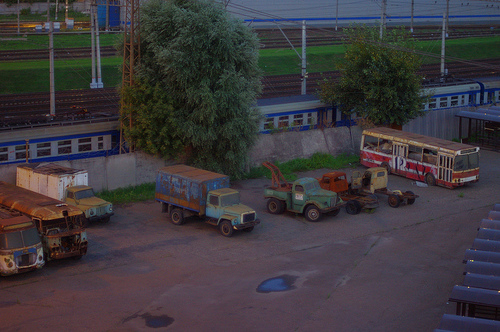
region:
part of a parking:
[428, 234, 443, 246]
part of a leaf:
[236, 134, 256, 154]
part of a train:
[298, 115, 300, 119]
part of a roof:
[464, 260, 474, 288]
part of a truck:
[219, 201, 226, 216]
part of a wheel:
[300, 212, 311, 222]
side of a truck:
[184, 186, 196, 196]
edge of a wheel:
[218, 218, 223, 229]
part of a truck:
[406, 153, 411, 163]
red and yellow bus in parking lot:
[348, 119, 484, 194]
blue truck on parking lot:
[142, 157, 262, 238]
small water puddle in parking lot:
[244, 261, 306, 299]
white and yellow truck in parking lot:
[8, 157, 123, 227]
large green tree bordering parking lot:
[123, 0, 260, 174]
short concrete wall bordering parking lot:
[1, 93, 497, 210]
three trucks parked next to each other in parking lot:
[255, 155, 425, 224]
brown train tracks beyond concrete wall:
[2, 16, 498, 63]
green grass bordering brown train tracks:
[1, 25, 496, 69]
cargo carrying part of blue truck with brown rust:
[152, 155, 231, 236]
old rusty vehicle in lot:
[362, 103, 462, 195]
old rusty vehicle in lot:
[4, 213, 48, 270]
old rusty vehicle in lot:
[39, 192, 96, 272]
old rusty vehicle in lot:
[72, 152, 148, 252]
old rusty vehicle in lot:
[166, 156, 248, 233]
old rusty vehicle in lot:
[257, 181, 340, 226]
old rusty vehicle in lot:
[332, 170, 362, 212]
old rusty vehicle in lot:
[372, 163, 431, 213]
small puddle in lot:
[224, 264, 321, 310]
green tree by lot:
[136, 26, 250, 154]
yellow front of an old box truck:
[61, 179, 111, 224]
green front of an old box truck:
[207, 178, 258, 235]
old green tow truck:
[260, 161, 340, 231]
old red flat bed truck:
[317, 165, 379, 213]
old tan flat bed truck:
[361, 161, 413, 219]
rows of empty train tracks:
[0, 16, 478, 128]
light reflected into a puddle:
[253, 264, 313, 313]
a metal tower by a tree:
[105, 2, 167, 152]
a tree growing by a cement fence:
[337, 27, 431, 147]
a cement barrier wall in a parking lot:
[119, 118, 347, 171]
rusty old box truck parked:
[152, 143, 260, 242]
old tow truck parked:
[249, 143, 343, 242]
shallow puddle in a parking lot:
[254, 261, 304, 307]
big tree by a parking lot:
[130, 13, 268, 167]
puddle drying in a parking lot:
[127, 289, 183, 330]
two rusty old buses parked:
[2, 185, 96, 280]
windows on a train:
[251, 102, 332, 125]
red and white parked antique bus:
[353, 110, 487, 200]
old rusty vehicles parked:
[3, 81, 492, 283]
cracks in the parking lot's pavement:
[329, 223, 398, 275]